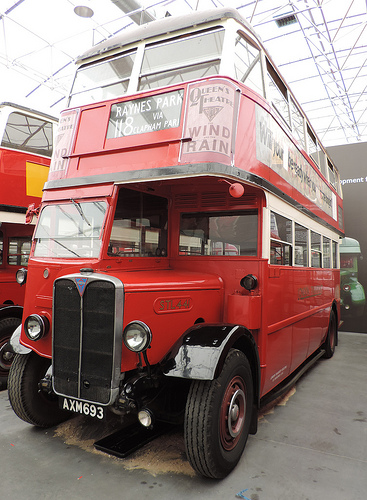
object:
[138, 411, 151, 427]
light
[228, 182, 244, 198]
mirror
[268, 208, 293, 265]
window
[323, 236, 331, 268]
window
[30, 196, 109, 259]
window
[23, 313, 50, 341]
headlight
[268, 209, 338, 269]
windows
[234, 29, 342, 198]
windows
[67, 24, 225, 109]
windows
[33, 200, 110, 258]
windows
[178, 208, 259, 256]
windows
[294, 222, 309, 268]
window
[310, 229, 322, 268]
window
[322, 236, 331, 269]
window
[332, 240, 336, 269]
window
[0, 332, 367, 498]
pavement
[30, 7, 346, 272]
double decker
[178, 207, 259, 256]
windshield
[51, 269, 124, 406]
vent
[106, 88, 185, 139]
sign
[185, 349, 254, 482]
wheel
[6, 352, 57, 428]
wheel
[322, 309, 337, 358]
tire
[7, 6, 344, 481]
bus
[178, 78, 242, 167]
sign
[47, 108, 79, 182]
sign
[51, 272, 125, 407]
grill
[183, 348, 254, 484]
tire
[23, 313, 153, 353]
headlights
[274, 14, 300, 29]
vent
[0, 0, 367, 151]
ceiling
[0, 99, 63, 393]
bus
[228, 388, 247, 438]
hubcap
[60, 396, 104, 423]
license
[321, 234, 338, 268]
window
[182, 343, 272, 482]
wheel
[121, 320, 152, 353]
headlight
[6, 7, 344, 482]
red bus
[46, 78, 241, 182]
sign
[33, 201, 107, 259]
reflection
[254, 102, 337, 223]
advertisement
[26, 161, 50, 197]
paint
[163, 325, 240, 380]
fender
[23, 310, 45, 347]
headlight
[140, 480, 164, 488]
oil spot